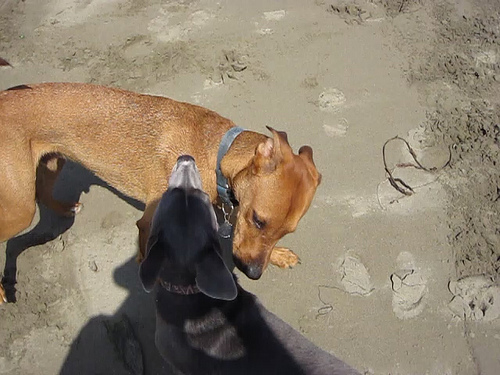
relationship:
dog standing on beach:
[0, 78, 329, 299] [1, 0, 499, 374]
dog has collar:
[0, 78, 329, 299] [207, 123, 254, 214]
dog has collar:
[114, 152, 373, 374] [142, 270, 235, 296]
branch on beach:
[369, 124, 460, 207] [1, 0, 499, 374]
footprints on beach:
[307, 71, 357, 142] [1, 0, 499, 374]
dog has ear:
[0, 78, 329, 299] [246, 123, 297, 180]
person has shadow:
[53, 189, 283, 374] [62, 193, 298, 370]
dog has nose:
[0, 78, 329, 299] [237, 256, 268, 282]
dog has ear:
[114, 152, 373, 374] [189, 243, 238, 302]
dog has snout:
[114, 152, 373, 374] [157, 149, 219, 199]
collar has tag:
[207, 123, 254, 214] [217, 215, 240, 239]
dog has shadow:
[0, 78, 329, 299] [10, 146, 125, 298]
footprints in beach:
[307, 71, 357, 142] [1, 0, 499, 374]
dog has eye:
[0, 78, 329, 299] [250, 209, 270, 232]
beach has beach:
[1, 0, 499, 374] [1, 0, 499, 374]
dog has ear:
[0, 78, 329, 299] [293, 136, 324, 185]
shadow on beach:
[62, 193, 298, 370] [1, 0, 499, 374]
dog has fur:
[0, 78, 329, 299] [77, 100, 191, 160]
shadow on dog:
[62, 193, 298, 370] [114, 152, 373, 374]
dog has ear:
[114, 152, 373, 374] [119, 231, 173, 295]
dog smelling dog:
[0, 78, 329, 299] [114, 152, 373, 374]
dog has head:
[0, 78, 329, 299] [227, 127, 332, 279]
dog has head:
[114, 152, 373, 374] [120, 154, 234, 298]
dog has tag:
[0, 78, 329, 299] [217, 215, 240, 239]